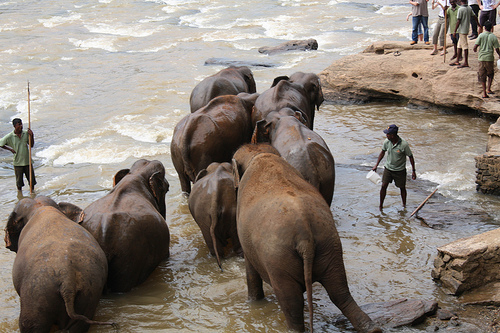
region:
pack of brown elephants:
[49, 69, 367, 294]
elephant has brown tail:
[301, 231, 334, 329]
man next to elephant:
[373, 121, 408, 240]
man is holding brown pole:
[3, 93, 60, 208]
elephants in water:
[9, 81, 402, 331]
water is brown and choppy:
[72, 65, 138, 141]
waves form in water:
[68, 6, 291, 118]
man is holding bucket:
[356, 164, 381, 194]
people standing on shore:
[392, 1, 499, 91]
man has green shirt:
[6, 125, 44, 175]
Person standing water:
[383, 120, 416, 211]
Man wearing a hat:
[380, 117, 408, 147]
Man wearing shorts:
[368, 162, 426, 215]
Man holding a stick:
[22, 80, 40, 170]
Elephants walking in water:
[162, 33, 341, 292]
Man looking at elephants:
[373, 116, 405, 150]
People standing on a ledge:
[412, 9, 494, 64]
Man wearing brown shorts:
[445, 25, 480, 56]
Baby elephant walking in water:
[175, 152, 245, 252]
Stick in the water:
[408, 186, 445, 223]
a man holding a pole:
[4, 115, 37, 201]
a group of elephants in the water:
[11, 64, 349, 330]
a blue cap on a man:
[380, 122, 402, 135]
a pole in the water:
[404, 182, 443, 232]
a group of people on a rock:
[403, 0, 499, 94]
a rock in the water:
[253, 33, 320, 58]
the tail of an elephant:
[293, 234, 317, 329]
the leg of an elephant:
[322, 274, 383, 330]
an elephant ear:
[144, 169, 176, 210]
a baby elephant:
[185, 152, 245, 273]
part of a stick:
[18, 155, 35, 182]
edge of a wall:
[467, 265, 477, 277]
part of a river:
[428, 217, 446, 230]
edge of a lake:
[441, 109, 443, 115]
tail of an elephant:
[311, 284, 322, 299]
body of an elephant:
[250, 190, 271, 256]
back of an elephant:
[268, 147, 289, 184]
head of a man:
[388, 125, 395, 132]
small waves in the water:
[61, 107, 152, 157]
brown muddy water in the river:
[158, 287, 219, 325]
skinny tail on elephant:
[294, 240, 336, 317]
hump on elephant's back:
[236, 144, 291, 191]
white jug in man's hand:
[365, 161, 382, 188]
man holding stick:
[12, 72, 50, 179]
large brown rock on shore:
[346, 51, 456, 103]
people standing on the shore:
[403, 3, 496, 72]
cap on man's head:
[372, 123, 409, 143]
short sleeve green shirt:
[6, 131, 57, 171]